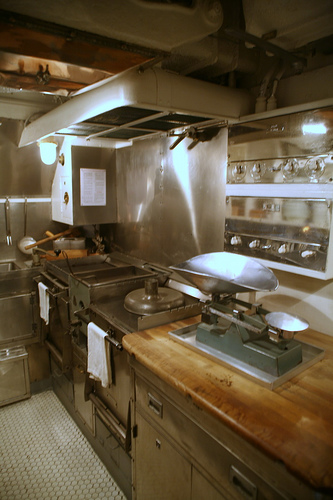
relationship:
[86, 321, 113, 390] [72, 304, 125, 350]
towel on rack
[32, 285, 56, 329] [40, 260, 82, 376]
towel hanging on stove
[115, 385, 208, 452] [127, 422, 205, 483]
drawer in cabinet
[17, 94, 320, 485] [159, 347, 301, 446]
kitchen with counter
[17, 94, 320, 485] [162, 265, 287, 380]
kitchen with scale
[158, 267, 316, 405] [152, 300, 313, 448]
scale on counter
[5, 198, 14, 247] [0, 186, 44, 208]
utensil hanging from wall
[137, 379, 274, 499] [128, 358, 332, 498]
drawer on cabinet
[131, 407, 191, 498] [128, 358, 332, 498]
door on cabinet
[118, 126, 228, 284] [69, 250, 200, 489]
back on kitchen stove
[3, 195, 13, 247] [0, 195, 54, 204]
utensil on rack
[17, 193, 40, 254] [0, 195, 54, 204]
utensil on rack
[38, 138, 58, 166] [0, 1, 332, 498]
bulb in kitchen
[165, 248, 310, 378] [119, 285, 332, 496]
scale on a counter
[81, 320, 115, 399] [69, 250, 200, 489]
towel hanging off of kitchen stove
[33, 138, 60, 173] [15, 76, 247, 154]
bulb hanging from hood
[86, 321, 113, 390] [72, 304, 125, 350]
towel over rack